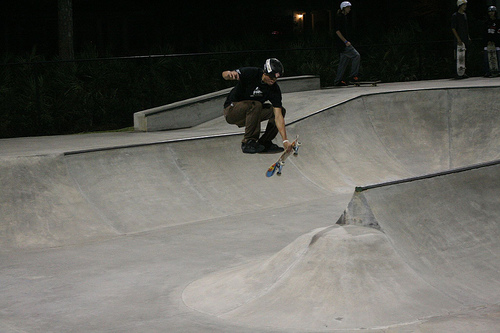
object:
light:
[294, 12, 307, 23]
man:
[222, 57, 293, 155]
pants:
[221, 99, 286, 147]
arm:
[264, 83, 287, 142]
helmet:
[338, 0, 351, 9]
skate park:
[0, 74, 499, 332]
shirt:
[221, 65, 285, 112]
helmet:
[262, 56, 285, 77]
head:
[260, 58, 281, 85]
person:
[447, 0, 475, 81]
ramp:
[360, 158, 498, 326]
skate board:
[264, 134, 304, 179]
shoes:
[255, 140, 287, 155]